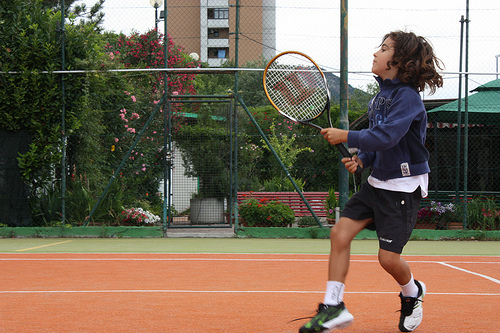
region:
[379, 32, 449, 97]
Hair is brown and curly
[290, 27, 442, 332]
Boy holding racket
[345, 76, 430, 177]
Sweater is blue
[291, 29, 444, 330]
Boy wearing shorts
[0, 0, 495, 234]
Fence is green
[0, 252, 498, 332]
Tennis court is orange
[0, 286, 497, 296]
White line on orange tennis court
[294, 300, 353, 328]
Shoe is green and white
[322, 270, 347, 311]
Sock is long and white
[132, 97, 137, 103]
Flower is pink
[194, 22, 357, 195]
the racket has strings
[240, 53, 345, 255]
the racket has strings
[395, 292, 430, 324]
Shoes are black and white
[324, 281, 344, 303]
White socks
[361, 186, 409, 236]
Tennis player is wearing black shorts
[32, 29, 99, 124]
Green bushes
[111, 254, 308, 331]
the tennis player is on the tennis court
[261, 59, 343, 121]
A tennis racket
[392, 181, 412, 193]
Tennis player is wearing white shirt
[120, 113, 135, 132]
pink flowers on the bushes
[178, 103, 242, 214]
Green gate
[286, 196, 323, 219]
A pink bench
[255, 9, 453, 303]
child holding tennis racket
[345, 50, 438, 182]
child wearing blue jacket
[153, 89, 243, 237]
door to enter tennis court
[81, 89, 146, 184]
fence around tennis court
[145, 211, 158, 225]
white flower plated on ground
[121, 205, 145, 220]
red flower planted on ground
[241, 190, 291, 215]
red flowers on green bush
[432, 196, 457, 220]
purple flowers planted on ground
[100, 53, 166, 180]
green tree with pink flowers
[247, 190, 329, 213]
red bench for sitting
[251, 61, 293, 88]
the racket has strings